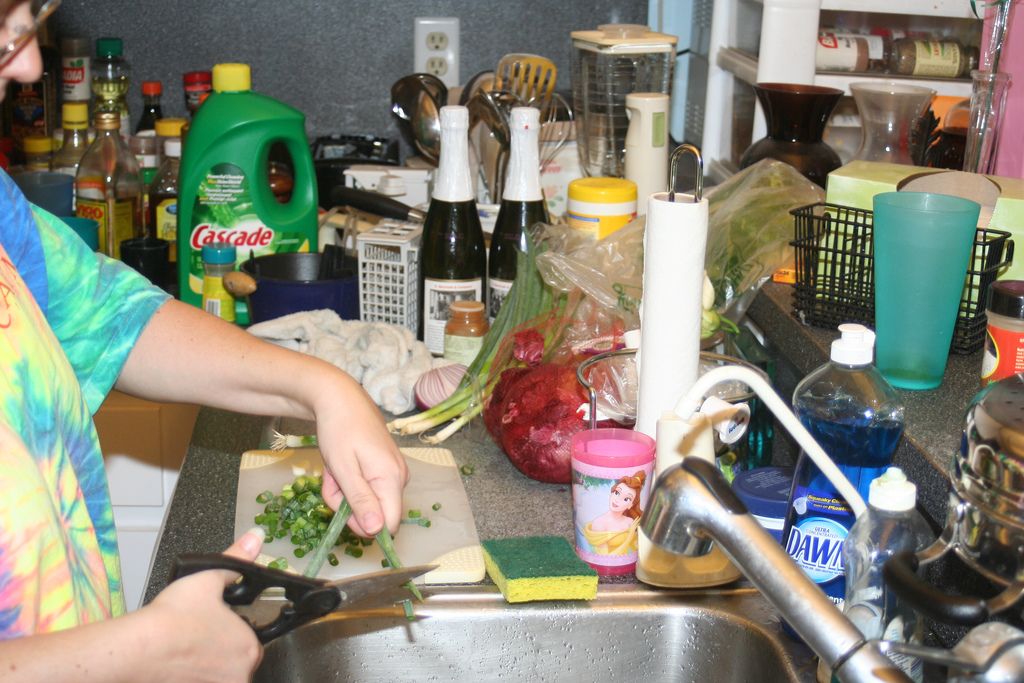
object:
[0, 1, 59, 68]
glasses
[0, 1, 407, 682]
human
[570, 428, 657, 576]
cup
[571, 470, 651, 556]
carton